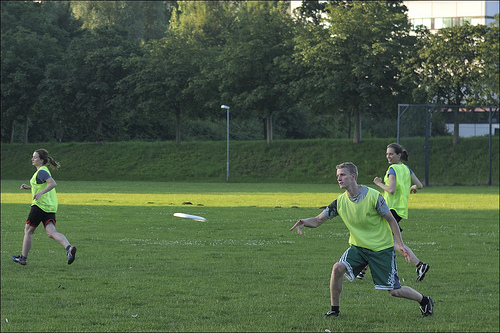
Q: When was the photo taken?
A: Daytime.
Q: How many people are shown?
A: Three.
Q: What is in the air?
A: Frisbee.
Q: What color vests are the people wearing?
A: Green.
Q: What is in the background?
A: Trees.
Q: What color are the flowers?
A: White.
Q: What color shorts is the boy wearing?
A: Green.